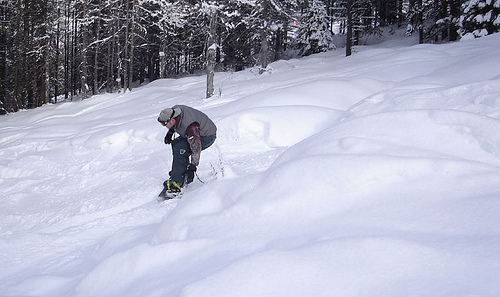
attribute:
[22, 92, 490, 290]
snow — white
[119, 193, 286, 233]
snow — white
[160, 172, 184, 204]
shoes — black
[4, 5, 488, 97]
trees — snow covered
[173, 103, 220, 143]
jacket — tan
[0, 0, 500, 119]
woods — large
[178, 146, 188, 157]
patch — white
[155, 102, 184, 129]
hat — tan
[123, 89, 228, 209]
man — ski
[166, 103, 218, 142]
jacket — gray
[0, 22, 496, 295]
snow — white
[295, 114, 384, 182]
mound — large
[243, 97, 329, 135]
mound — large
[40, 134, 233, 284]
snow — white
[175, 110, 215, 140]
vest — gray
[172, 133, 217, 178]
pants — blue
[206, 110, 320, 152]
pile — large